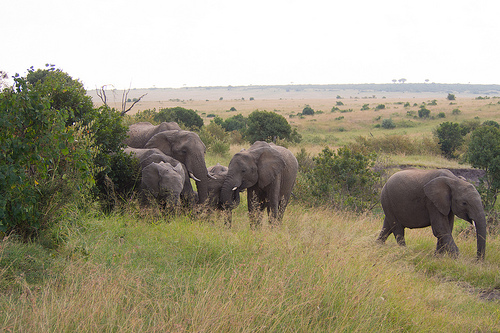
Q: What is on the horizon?
A: Mountains.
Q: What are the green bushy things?
A: Bushes.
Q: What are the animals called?
A: Elephants.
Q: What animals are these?
A: Elephants.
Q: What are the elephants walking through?
A: Grass.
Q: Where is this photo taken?
A: On a grassy plain.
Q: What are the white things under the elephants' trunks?
A: Tusks.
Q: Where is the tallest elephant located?
A: On the left.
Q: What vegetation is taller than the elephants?
A: Trees.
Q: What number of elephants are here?
A: 6.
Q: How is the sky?
A: Clear.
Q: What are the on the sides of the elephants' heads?
A: Ears.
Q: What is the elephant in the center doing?
A: Eating.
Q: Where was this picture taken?
A: In a field.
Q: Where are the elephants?
A: In the grass.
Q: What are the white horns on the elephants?
A: Tusks.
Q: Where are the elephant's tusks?
A: On either side of the elephants' trunks.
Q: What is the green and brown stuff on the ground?
A: Grass.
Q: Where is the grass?
A: On the ground.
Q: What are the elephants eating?
A: Grass.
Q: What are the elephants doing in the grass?
A: Eating.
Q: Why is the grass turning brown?
A: It is dying.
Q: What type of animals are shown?
A: Elephants.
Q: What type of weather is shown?
A: Clear.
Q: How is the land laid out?
A: Flat.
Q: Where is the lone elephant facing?
A: Right.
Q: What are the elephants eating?
A: Grass.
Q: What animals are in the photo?
A: Elephants.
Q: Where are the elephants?
A: In the wilderness.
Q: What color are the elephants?
A: Grey.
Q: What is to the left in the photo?
A: Bushes.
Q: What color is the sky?
A: Whitish-grey.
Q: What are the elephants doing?
A: Walking.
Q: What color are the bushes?
A: Green.